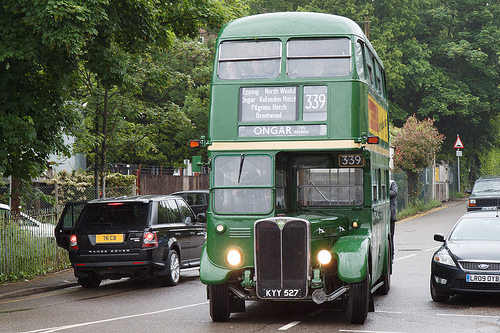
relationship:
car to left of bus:
[49, 191, 214, 291] [192, 11, 401, 322]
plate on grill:
[261, 288, 301, 299] [254, 218, 307, 298]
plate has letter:
[261, 288, 301, 299] [263, 289, 271, 297]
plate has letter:
[261, 288, 301, 299] [266, 288, 278, 296]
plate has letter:
[261, 288, 301, 299] [276, 287, 282, 296]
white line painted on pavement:
[279, 319, 306, 331] [1, 194, 498, 331]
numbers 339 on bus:
[304, 94, 326, 110] [192, 11, 401, 322]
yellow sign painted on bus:
[367, 93, 389, 142] [192, 11, 401, 322]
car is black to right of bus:
[429, 208, 498, 303] [192, 11, 401, 322]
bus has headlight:
[192, 11, 401, 322] [225, 247, 245, 267]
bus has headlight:
[192, 11, 401, 322] [314, 248, 332, 268]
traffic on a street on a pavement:
[44, 0, 500, 331] [1, 194, 498, 331]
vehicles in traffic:
[433, 144, 483, 308] [50, 7, 481, 330]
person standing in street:
[387, 164, 402, 266] [390, 212, 440, 332]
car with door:
[49, 191, 214, 291] [49, 199, 89, 249]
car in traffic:
[49, 191, 214, 291] [50, 7, 481, 330]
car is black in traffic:
[429, 208, 498, 303] [50, 7, 481, 330]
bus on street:
[198, 10, 399, 322] [403, 212, 463, 332]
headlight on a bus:
[225, 247, 245, 267] [192, 11, 401, 322]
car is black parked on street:
[429, 208, 498, 303] [394, 219, 437, 330]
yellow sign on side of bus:
[367, 93, 389, 142] [192, 11, 401, 322]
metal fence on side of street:
[3, 187, 123, 273] [400, 218, 475, 310]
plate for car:
[93, 232, 125, 244] [49, 191, 214, 291]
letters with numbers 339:
[245, 85, 301, 119] [304, 94, 326, 110]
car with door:
[38, 191, 219, 282] [49, 199, 89, 249]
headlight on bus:
[225, 247, 245, 267] [192, 11, 401, 322]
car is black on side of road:
[429, 208, 498, 303] [37, 257, 277, 331]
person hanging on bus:
[387, 164, 399, 277] [197, 28, 399, 328]